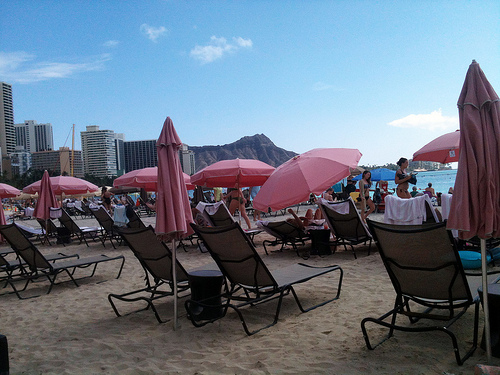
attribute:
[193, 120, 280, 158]
mountain — distant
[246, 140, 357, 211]
umbrella — open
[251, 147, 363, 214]
umbrella — slightly tilted, red, opened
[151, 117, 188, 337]
umbrella — closed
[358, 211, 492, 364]
chair — empty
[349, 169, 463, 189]
water — blue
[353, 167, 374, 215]
woman — walking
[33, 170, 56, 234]
umbrella — closed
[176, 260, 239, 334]
table — small , black 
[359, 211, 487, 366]
chaise lounge — vacant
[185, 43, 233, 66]
cloud — white, light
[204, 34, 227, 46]
cloud — white, light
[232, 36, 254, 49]
cloud — white, light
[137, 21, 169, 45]
cloud — white, light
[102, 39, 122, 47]
cloud — white, light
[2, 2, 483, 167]
sky — blue, clear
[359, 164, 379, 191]
hair — down